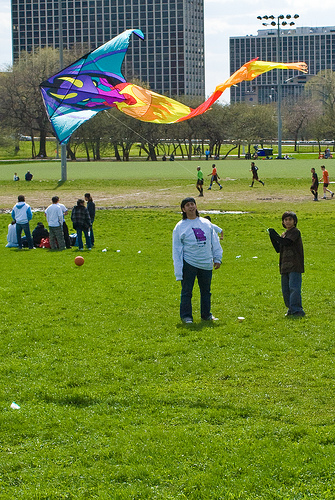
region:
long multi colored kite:
[41, 22, 309, 145]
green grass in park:
[71, 333, 242, 474]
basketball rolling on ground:
[72, 250, 85, 267]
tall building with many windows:
[11, 0, 206, 138]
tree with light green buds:
[9, 45, 71, 167]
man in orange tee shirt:
[207, 161, 223, 192]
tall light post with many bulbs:
[255, 6, 304, 162]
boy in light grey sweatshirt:
[169, 190, 226, 332]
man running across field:
[245, 161, 268, 189]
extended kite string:
[113, 110, 279, 238]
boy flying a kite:
[154, 163, 334, 340]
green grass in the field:
[58, 363, 270, 468]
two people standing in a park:
[150, 200, 315, 334]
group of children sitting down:
[2, 180, 106, 252]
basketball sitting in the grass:
[69, 253, 91, 271]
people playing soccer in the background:
[192, 160, 333, 210]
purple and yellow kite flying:
[33, 21, 318, 160]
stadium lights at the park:
[253, 10, 303, 164]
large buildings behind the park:
[7, 5, 334, 108]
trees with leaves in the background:
[9, 64, 333, 169]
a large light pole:
[252, 14, 299, 159]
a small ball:
[71, 250, 86, 265]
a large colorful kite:
[35, 27, 311, 144]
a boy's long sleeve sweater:
[267, 227, 304, 273]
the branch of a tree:
[110, 142, 122, 162]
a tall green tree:
[308, 69, 333, 154]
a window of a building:
[162, 33, 167, 39]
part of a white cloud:
[205, 20, 252, 34]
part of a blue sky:
[304, 13, 334, 24]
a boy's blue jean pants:
[278, 272, 303, 313]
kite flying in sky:
[21, 24, 320, 145]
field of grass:
[37, 364, 328, 472]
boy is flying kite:
[38, 16, 312, 335]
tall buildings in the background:
[5, 4, 333, 110]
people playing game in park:
[0, 143, 330, 200]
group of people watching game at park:
[2, 155, 167, 254]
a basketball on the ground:
[46, 252, 148, 310]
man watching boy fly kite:
[39, 68, 326, 340]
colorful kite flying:
[25, 31, 307, 154]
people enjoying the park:
[7, 76, 326, 367]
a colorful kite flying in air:
[36, 29, 311, 152]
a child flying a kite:
[221, 54, 332, 325]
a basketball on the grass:
[63, 252, 96, 275]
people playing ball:
[171, 141, 333, 203]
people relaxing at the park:
[7, 190, 101, 251]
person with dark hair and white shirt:
[166, 189, 233, 353]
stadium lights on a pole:
[252, 12, 301, 53]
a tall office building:
[142, 3, 225, 110]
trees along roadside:
[184, 102, 306, 159]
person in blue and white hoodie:
[9, 194, 37, 249]